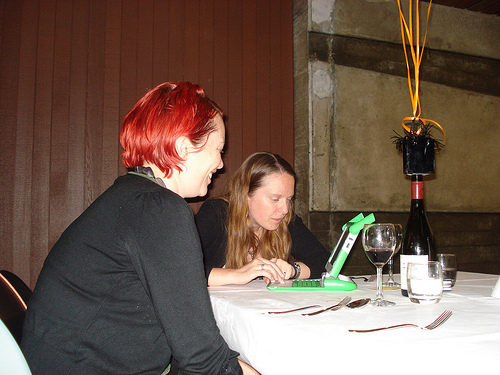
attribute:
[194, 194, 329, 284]
top — girls, black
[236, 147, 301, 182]
hair — brown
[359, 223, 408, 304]
glasses — clear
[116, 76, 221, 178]
hair — red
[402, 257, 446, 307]
glass — short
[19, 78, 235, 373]
woman — smiling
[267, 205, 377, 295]
computer — green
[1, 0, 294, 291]
wall — wood, panel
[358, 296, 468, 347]
fork — silver, metal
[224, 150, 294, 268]
hair — brown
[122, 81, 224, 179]
red hair — short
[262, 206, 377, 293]
laptop — green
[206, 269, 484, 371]
tablecloth — white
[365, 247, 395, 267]
wine — red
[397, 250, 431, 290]
label — white